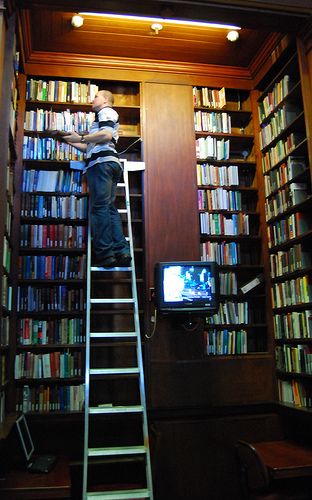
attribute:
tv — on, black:
[151, 260, 223, 318]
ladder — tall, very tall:
[80, 156, 155, 498]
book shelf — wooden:
[195, 185, 264, 214]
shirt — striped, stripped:
[79, 106, 126, 177]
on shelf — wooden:
[21, 99, 146, 138]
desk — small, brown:
[242, 438, 311, 499]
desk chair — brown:
[230, 435, 271, 498]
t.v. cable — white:
[139, 306, 160, 342]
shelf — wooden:
[13, 249, 151, 289]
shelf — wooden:
[256, 61, 301, 126]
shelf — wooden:
[196, 294, 272, 327]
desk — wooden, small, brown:
[4, 444, 76, 499]